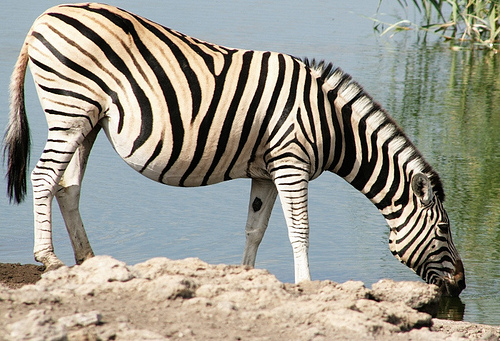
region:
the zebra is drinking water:
[17, 20, 472, 297]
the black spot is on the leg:
[237, 190, 276, 221]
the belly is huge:
[108, 114, 264, 214]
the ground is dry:
[104, 243, 358, 334]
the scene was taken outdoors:
[0, 17, 493, 338]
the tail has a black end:
[7, 64, 36, 203]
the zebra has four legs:
[40, 10, 457, 296]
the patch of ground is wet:
[17, 265, 39, 283]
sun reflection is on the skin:
[17, 12, 259, 134]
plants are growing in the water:
[411, 7, 499, 60]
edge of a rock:
[227, 290, 239, 307]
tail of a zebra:
[13, 129, 29, 149]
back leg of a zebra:
[52, 146, 54, 158]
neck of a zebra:
[386, 191, 393, 207]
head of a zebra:
[436, 222, 443, 240]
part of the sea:
[413, 15, 426, 70]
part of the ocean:
[183, 212, 193, 235]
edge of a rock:
[206, 287, 223, 320]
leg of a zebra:
[288, 184, 294, 227]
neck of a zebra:
[369, 176, 391, 208]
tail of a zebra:
[17, 157, 21, 169]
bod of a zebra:
[188, 116, 218, 127]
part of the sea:
[181, 205, 201, 220]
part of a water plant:
[431, 17, 453, 84]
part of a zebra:
[309, 107, 341, 123]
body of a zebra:
[304, 78, 327, 90]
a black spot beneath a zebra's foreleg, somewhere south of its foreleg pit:
[245, 192, 269, 218]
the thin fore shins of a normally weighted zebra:
[238, 242, 320, 289]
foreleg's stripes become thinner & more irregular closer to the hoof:
[269, 147, 319, 251]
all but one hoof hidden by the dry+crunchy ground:
[24, 236, 324, 307]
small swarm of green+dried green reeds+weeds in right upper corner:
[365, 0, 498, 65]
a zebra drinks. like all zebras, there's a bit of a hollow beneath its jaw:
[377, 226, 478, 303]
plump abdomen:
[93, 84, 263, 189]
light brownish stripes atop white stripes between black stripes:
[30, 8, 286, 186]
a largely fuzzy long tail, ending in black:
[0, 38, 30, 203]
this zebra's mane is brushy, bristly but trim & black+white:
[299, 48, 452, 207]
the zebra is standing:
[7, 2, 468, 296]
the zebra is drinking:
[357, 155, 471, 316]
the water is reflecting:
[364, 15, 484, 232]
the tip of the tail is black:
[0, 18, 30, 203]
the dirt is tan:
[65, 232, 380, 338]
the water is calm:
[335, 10, 479, 199]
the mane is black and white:
[303, 40, 444, 198]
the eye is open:
[425, 207, 455, 242]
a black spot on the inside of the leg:
[244, 182, 269, 224]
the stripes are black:
[98, 39, 333, 135]